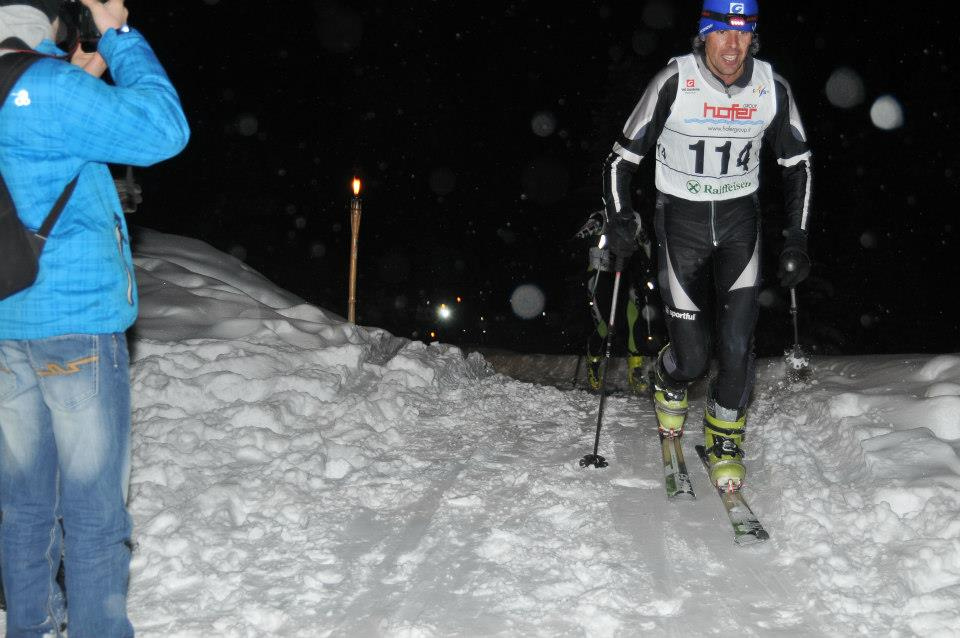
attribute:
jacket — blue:
[0, 30, 204, 333]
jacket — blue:
[3, 20, 192, 340]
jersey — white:
[652, 52, 779, 198]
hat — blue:
[690, 0, 759, 37]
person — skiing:
[575, 170, 655, 392]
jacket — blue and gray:
[602, 56, 820, 239]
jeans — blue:
[0, 329, 138, 636]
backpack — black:
[2, 50, 84, 295]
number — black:
[687, 131, 751, 184]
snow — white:
[108, 222, 954, 637]